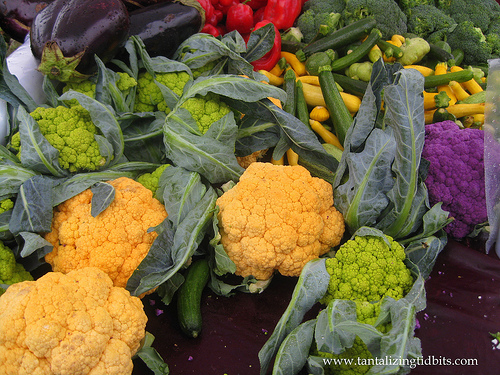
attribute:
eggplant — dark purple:
[29, 0, 203, 85]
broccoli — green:
[369, 0, 409, 36]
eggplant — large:
[2, 4, 226, 79]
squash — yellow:
[288, 58, 375, 128]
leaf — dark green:
[256, 258, 328, 373]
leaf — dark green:
[271, 319, 313, 373]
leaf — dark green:
[371, 298, 419, 374]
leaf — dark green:
[311, 300, 381, 353]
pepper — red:
[199, 3, 311, 78]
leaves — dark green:
[138, 96, 220, 275]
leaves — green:
[9, 122, 99, 228]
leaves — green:
[149, 115, 324, 293]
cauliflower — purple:
[422, 115, 499, 229]